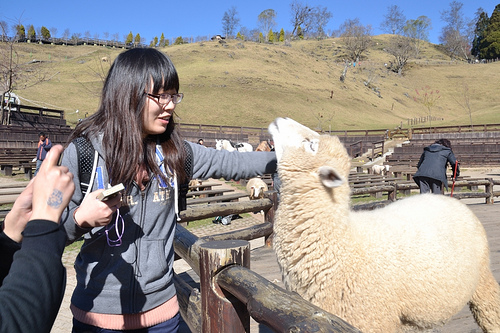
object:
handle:
[450, 160, 458, 196]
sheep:
[262, 112, 498, 328]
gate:
[182, 223, 350, 333]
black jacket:
[0, 211, 69, 331]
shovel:
[448, 159, 460, 201]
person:
[0, 140, 71, 332]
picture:
[0, 0, 500, 333]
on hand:
[33, 145, 74, 225]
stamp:
[48, 187, 64, 208]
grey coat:
[44, 127, 289, 310]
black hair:
[84, 46, 189, 197]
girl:
[62, 43, 272, 333]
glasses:
[146, 93, 190, 105]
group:
[211, 136, 271, 198]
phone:
[92, 181, 129, 204]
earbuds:
[103, 208, 127, 247]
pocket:
[83, 244, 118, 282]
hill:
[217, 39, 358, 110]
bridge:
[17, 30, 126, 47]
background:
[187, 18, 477, 62]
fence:
[162, 199, 271, 242]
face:
[141, 73, 178, 134]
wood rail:
[226, 270, 318, 329]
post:
[193, 226, 254, 332]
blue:
[56, 3, 73, 23]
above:
[12, 1, 263, 37]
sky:
[197, 6, 339, 26]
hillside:
[399, 34, 452, 63]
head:
[266, 115, 354, 187]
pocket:
[145, 235, 171, 279]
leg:
[475, 278, 500, 333]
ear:
[319, 168, 345, 188]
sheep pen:
[164, 94, 500, 333]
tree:
[338, 18, 370, 76]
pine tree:
[474, 9, 495, 71]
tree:
[258, 7, 283, 37]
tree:
[220, 4, 241, 42]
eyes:
[154, 93, 164, 99]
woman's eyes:
[170, 95, 180, 100]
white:
[280, 133, 289, 140]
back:
[33, 168, 65, 213]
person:
[413, 138, 459, 197]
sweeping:
[442, 144, 467, 196]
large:
[33, 37, 359, 127]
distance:
[371, 30, 483, 43]